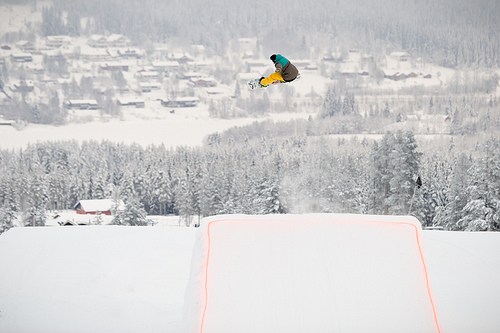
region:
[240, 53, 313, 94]
a snowboarder doing a trick in the air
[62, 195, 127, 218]
a building with snow on the roof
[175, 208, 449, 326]
a jump ramp made of snow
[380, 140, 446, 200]
trees with snow on them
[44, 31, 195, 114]
a village with snow in the winter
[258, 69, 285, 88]
a person wearing yellow snow pants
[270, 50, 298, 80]
a person wearing a green and brown coat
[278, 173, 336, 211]
the dust of snow in the air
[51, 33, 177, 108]
houses on a hill side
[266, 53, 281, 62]
the head of a person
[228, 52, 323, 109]
He is snow boarding.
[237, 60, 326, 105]
He is doing a trick.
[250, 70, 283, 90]
The pants are yellow.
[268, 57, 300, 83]
His jacket is gray.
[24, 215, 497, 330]
The ground is snow covered.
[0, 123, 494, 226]
The trees are snow covered.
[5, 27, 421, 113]
The houses are snow covered.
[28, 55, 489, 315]
He is in the air.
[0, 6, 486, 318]
He is snow boarding.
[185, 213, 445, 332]
Pink paint is on the ground.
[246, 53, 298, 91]
the person is in the air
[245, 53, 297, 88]
the person is on a board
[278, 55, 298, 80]
the person has a gray and blue coat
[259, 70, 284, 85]
the person has orange pants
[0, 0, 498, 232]
the trees are full of snow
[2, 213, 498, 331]
the ground is full of snow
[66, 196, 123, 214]
the roof is full of snow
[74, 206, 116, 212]
the building is brown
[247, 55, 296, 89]
the person is snowboarding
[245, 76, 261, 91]
the board is white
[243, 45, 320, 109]
person jumps on snowboard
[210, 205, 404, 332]
orange lines on ramp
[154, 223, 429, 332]
white snow on ramp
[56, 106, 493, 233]
tall green pine trees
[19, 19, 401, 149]
many buildings below ramp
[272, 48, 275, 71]
person has dark hat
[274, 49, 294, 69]
person has green coat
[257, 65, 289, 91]
person has orange pants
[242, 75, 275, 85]
person has white snowboard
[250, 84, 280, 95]
person has black boots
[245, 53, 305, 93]
Person catching air on snowboard.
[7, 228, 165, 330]
White snow covering ground.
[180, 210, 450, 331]
Jumping ramp with snow on it.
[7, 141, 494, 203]
Trees covered with snow.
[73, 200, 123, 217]
Red house surrounded by trees.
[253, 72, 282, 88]
Yellow pants of snowboarder.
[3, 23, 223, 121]
Multiple houses in background.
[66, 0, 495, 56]
Trees going down mountain side.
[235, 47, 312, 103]
Snowboarder doing a trick in air.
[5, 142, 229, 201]
Group of pine trees covered with snow.